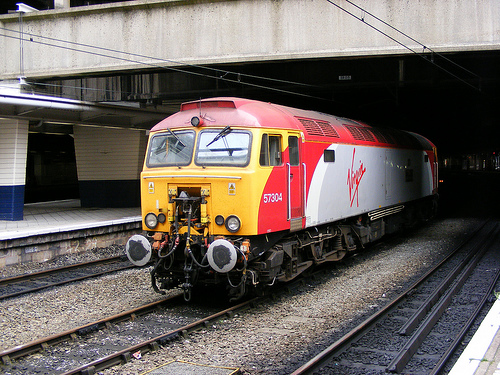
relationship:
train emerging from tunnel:
[125, 97, 441, 305] [28, 50, 500, 219]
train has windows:
[125, 97, 441, 305] [147, 129, 251, 167]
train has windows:
[125, 97, 441, 305] [259, 131, 300, 168]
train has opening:
[125, 97, 441, 305] [178, 186, 203, 224]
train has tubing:
[125, 97, 441, 305] [157, 202, 208, 265]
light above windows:
[191, 117, 202, 126] [147, 129, 251, 167]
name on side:
[347, 146, 368, 209] [257, 99, 440, 235]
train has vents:
[125, 97, 441, 305] [299, 115, 385, 143]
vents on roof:
[299, 115, 385, 143] [153, 95, 436, 146]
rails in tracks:
[1, 301, 209, 375] [1, 284, 235, 374]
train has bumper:
[125, 97, 441, 305] [124, 233, 237, 273]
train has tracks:
[125, 97, 441, 305] [1, 284, 235, 374]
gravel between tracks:
[85, 218, 470, 375] [1, 222, 500, 375]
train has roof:
[125, 97, 441, 305] [153, 95, 436, 146]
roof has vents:
[153, 95, 436, 146] [299, 115, 385, 143]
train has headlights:
[125, 97, 441, 305] [145, 210, 242, 234]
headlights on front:
[145, 210, 242, 234] [142, 108, 257, 292]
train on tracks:
[125, 97, 441, 305] [1, 284, 235, 374]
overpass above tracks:
[2, 1, 498, 82] [1, 222, 500, 375]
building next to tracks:
[24, 129, 80, 204] [1, 284, 235, 374]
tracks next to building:
[1, 222, 500, 375] [24, 129, 80, 204]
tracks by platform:
[1, 222, 500, 375] [1, 199, 144, 243]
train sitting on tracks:
[125, 97, 441, 305] [1, 284, 235, 374]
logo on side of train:
[344, 146, 369, 206] [125, 97, 441, 305]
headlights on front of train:
[145, 210, 242, 234] [125, 97, 441, 305]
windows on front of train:
[147, 129, 251, 167] [125, 97, 441, 305]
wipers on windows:
[168, 120, 231, 146] [147, 129, 251, 167]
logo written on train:
[344, 146, 369, 206] [125, 97, 441, 305]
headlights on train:
[145, 210, 242, 234] [125, 97, 441, 305]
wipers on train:
[168, 120, 231, 146] [125, 97, 441, 305]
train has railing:
[125, 97, 441, 305] [288, 160, 309, 222]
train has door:
[125, 97, 441, 305] [288, 131, 302, 217]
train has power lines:
[125, 97, 441, 305] [1, 1, 482, 99]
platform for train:
[1, 199, 144, 243] [125, 97, 441, 305]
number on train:
[263, 193, 286, 202] [125, 97, 441, 305]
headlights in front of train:
[145, 210, 242, 234] [125, 97, 441, 305]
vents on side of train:
[299, 115, 385, 143] [125, 97, 441, 305]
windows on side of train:
[259, 131, 300, 168] [125, 97, 441, 305]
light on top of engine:
[191, 117, 202, 126] [125, 97, 441, 305]